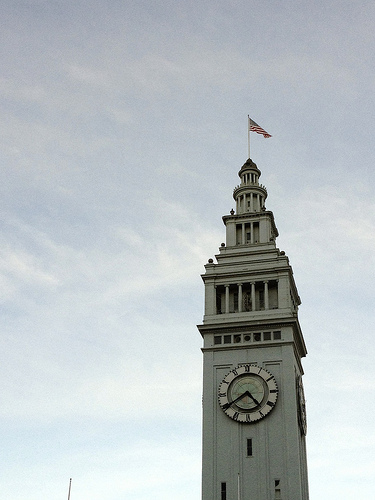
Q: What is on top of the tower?
A: A flag.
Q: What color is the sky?
A: Blue.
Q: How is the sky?
A: Has clouds.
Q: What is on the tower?
A: A clock.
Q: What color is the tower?
A: White.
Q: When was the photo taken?
A: Daytime.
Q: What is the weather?
A: Windy.